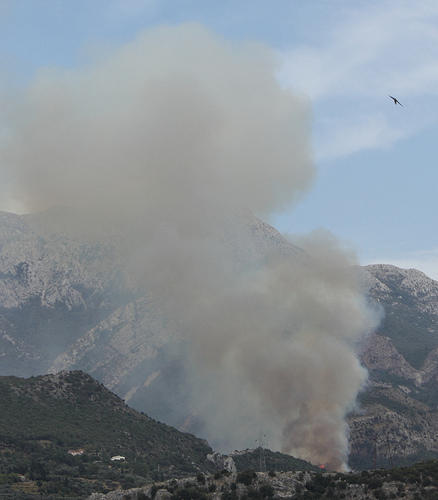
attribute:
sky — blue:
[1, 8, 437, 295]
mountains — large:
[0, 206, 437, 498]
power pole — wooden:
[366, 436, 381, 475]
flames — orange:
[318, 464, 326, 469]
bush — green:
[306, 475, 329, 493]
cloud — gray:
[0, 10, 396, 462]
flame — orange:
[315, 461, 326, 467]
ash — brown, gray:
[233, 390, 350, 463]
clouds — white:
[53, 76, 350, 461]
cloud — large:
[7, 22, 381, 476]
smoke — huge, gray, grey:
[6, 23, 380, 471]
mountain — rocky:
[0, 182, 436, 470]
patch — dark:
[0, 285, 147, 377]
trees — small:
[183, 472, 206, 494]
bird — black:
[379, 82, 418, 124]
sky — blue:
[351, 132, 416, 206]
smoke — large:
[18, 37, 382, 418]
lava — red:
[309, 455, 334, 479]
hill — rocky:
[1, 192, 437, 497]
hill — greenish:
[1, 368, 437, 498]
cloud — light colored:
[280, 3, 427, 161]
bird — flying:
[388, 92, 405, 110]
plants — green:
[0, 392, 215, 463]